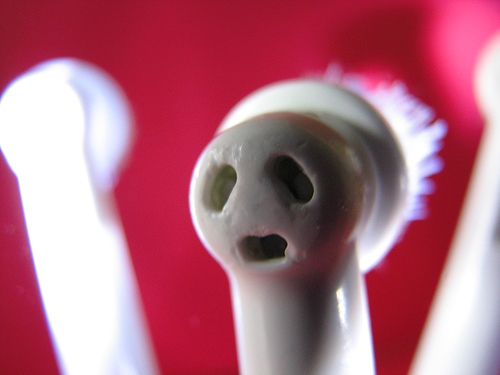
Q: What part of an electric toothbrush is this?
A: The end.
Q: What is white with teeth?
A: Electric toothbrush.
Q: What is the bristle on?
A: A toothbrush.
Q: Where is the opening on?
A: An electric toothbrush.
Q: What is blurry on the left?
A: A white shaped object.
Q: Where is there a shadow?
A: On the toothbrush.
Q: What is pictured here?
A: Electric toothbrush with an opening.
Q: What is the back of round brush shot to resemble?
A: A face.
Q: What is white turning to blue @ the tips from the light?
A: Round bristles.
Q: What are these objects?
A: Toothbrushes.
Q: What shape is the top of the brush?
A: Circle.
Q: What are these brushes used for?
A: Cleaning teeth.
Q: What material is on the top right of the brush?
A: Bristles.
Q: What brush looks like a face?
A: The middle.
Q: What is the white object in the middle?
A: A brush.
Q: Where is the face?
A: On the middle brush.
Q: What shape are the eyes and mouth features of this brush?
A: Oval.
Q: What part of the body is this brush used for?
A: Teeth.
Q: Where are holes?
A: In model.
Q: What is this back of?
A: Toothbrush.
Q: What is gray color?
A: Brush back.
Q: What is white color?
A: Bristles.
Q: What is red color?
A: Backdrop.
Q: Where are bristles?
A: On brush.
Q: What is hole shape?
A: Oblong.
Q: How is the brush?
A: Off white.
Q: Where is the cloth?
A: Behind brushes.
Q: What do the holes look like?
A: Face.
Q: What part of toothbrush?
A: Head.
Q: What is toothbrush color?
A: White.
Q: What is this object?
A: Toothbrush.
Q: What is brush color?
A: White.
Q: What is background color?
A: Red.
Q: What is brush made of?
A: Plastic.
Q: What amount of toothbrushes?
A: Two.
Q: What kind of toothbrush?
A: Electric.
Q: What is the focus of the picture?
A: A toothbrush.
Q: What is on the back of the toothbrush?
A: Three holes.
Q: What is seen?
A: Brush.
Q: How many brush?
A: 3.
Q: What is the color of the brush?
A: White.